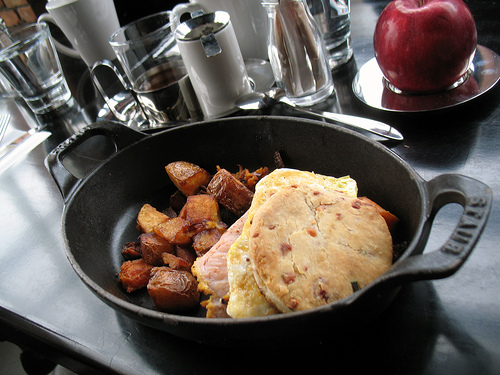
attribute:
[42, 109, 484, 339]
pan — metallic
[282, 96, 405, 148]
knife — silver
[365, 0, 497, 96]
apple — big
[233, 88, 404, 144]
spoon — silver